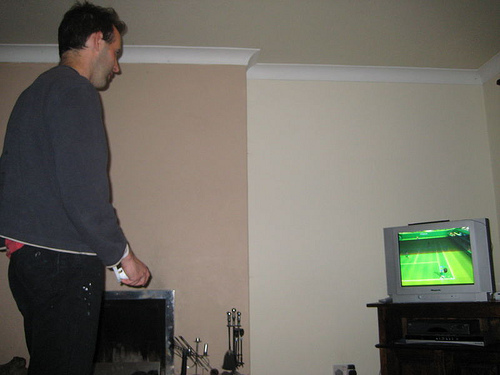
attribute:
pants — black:
[3, 245, 105, 372]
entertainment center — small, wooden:
[366, 299, 499, 374]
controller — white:
[110, 256, 127, 285]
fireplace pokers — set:
[223, 306, 248, 369]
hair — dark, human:
[57, 0, 128, 58]